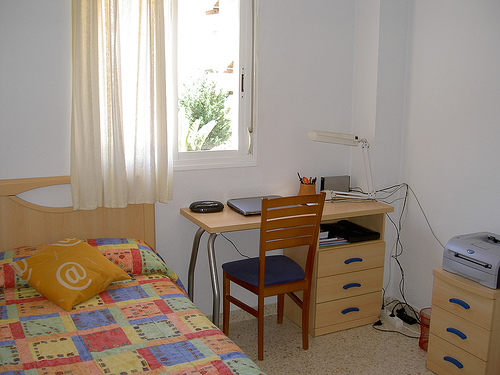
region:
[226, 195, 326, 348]
Brown chair at desk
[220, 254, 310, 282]
Blue cushion on chair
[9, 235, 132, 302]
Yellow pillow on bed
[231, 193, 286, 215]
Laptop computer on desk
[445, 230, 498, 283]
Gray printer on stand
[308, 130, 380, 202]
White desk lamp on desk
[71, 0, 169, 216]
White curtain on window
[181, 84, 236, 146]
Green plant outside window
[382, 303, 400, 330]
White surge protector near desk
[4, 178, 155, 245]
Tan headboard on bed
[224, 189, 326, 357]
a chair of dark wook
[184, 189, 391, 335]
small desk of light wood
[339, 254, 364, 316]
door handles of three drawers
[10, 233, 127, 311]
a pillow with an 'at' symbol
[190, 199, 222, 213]
a modem on the desk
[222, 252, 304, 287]
dark cushion on the chair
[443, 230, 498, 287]
printer on another surface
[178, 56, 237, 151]
foliage outside the window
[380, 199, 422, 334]
a gathering of wires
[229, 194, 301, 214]
closed laptop sitting on the desk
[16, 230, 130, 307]
yellow pillow with @ sign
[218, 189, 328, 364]
a wooden chair with a blue cushion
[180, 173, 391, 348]
a clean orderly desk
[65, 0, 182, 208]
white curtains hanging near window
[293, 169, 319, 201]
a yellow pencil holder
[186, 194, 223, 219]
a black alarm clock on desk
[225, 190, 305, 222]
a closed laptop sitting on desk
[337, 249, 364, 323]
blue handles on desk drawers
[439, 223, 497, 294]
printer on top of drawers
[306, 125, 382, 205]
a white desk lamp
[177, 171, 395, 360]
a kid-sized desk is positioned against the wall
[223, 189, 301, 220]
a laptop computer on the desk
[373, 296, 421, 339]
a sensible power cord for all the electronics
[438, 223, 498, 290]
a printer set up on a nearby chest of drawers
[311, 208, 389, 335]
the kid desk has three attached drawers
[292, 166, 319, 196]
pencil holder on the desk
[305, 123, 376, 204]
fluorescent lamp on the desk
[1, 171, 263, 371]
twin bed beside the desk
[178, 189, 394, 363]
A desk and chair.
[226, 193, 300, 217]
A laptop on a desk.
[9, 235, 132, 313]
A pillow on a bed.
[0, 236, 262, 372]
A quilt on a bed.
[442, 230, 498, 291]
A printer on a table.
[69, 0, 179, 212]
A curtain on a window.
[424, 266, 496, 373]
A nightstand on the floor.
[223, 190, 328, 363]
A brown wood chair.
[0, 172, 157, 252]
A headboard on a bed.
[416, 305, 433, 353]
Part of a trash can.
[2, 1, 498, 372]
Clean and tidy bedroom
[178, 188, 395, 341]
Light brown small desk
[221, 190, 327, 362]
Chair has blue cushion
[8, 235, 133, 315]
Square yellow pillow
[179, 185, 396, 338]
Desk has a laptop on top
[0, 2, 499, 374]
bedroom has bed and desk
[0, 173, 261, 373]
Neatly made bed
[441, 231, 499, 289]
Gray computer printer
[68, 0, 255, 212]
Window has curtain